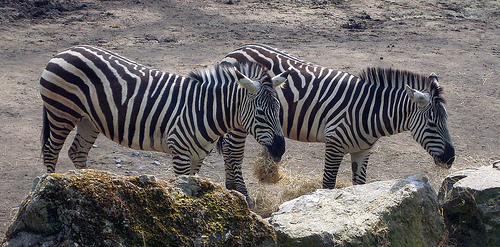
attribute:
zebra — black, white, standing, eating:
[31, 47, 283, 188]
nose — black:
[269, 135, 288, 159]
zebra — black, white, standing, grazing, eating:
[220, 45, 455, 189]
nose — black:
[436, 146, 455, 170]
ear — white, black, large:
[236, 71, 256, 91]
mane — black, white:
[196, 68, 254, 77]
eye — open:
[256, 105, 266, 118]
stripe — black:
[337, 75, 347, 104]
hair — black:
[39, 109, 46, 146]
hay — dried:
[256, 160, 281, 182]